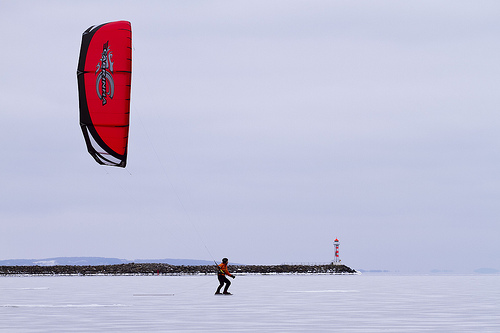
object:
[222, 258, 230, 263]
helmet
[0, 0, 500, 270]
sky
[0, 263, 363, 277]
peninsula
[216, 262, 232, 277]
shirt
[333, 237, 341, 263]
light house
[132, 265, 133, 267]
rocks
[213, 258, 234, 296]
man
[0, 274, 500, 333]
ice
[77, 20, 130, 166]
parachute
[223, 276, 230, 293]
legs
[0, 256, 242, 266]
mountain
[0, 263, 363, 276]
shore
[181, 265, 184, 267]
rocks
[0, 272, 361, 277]
strip